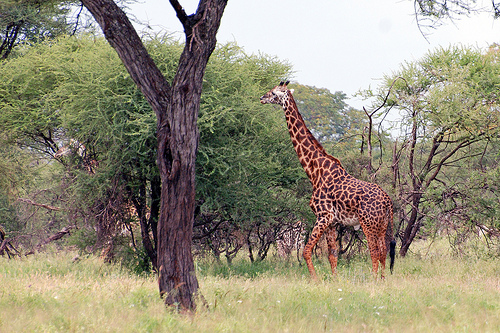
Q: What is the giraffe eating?
A: Leaves.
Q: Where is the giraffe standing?
A: In the grass.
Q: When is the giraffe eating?
A: In the daytime.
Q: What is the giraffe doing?
A: Eating leaves.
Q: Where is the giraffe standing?
A: Next to the trees.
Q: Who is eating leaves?
A: The giraffe.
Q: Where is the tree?
A: Next to the giraffe.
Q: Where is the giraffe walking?
A: In the grass.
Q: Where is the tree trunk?
A: Near the giraffe.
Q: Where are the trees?
A: In the field.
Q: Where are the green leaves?
A: On the tree.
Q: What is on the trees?
A: Green leaves.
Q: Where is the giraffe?
A: On the field.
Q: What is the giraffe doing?
A: Walking.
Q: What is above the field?
A: Sky.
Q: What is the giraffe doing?
A: Eatting leaves.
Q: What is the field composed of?
A: Tall grass.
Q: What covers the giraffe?
A: Spots.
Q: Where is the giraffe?
A: In the field.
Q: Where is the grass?
A: In the field.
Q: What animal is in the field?
A: Giraffe.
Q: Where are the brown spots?
A: On the giraffe.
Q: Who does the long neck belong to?
A: Giraffe.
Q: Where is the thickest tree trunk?
A: Left of the giraffe.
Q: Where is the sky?
A: Above the trees.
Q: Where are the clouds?
A: In the sky.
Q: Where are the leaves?
A: On the trees.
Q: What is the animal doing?
A: Eating.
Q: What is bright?
A: The sky.